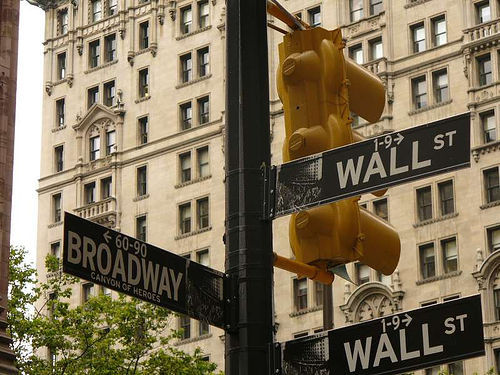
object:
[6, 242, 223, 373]
tree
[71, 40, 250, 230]
white building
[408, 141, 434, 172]
ground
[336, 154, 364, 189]
letter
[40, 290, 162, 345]
leaves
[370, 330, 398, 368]
white letter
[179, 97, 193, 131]
windows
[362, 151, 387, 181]
white letter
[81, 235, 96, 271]
white letter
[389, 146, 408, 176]
white letter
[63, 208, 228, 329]
sign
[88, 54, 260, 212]
wall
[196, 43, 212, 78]
windows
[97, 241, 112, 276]
letter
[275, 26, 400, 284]
signal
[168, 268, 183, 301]
letter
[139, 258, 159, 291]
letter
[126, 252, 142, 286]
letter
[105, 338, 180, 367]
leaves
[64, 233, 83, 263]
lettering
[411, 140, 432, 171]
lettering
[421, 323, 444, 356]
lettering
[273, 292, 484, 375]
sign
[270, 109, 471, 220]
sign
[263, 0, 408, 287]
street signal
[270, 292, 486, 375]
street sign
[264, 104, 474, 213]
street sign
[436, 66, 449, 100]
window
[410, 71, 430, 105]
window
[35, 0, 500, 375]
building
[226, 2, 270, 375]
pole